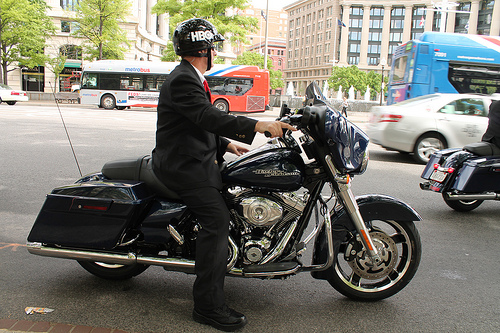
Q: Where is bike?
A: Road.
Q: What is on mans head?
A: Helmet.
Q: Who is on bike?
A: The man.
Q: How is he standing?
A: Bent.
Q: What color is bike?
A: Black.